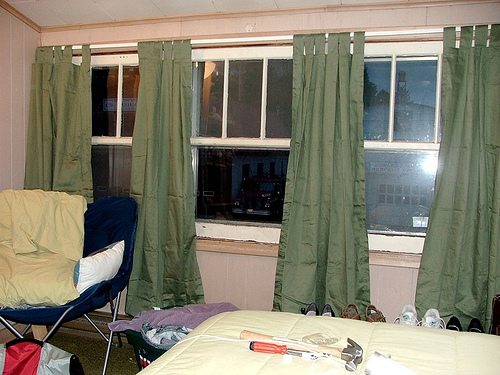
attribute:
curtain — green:
[122, 36, 204, 319]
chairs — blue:
[19, 151, 216, 373]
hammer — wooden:
[236, 327, 366, 374]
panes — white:
[36, 55, 495, 260]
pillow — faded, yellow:
[0, 183, 83, 310]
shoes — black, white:
[305, 299, 337, 318]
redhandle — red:
[251, 341, 288, 353]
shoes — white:
[403, 291, 447, 343]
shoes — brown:
[344, 301, 384, 323]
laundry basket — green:
[124, 319, 174, 371]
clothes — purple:
[101, 300, 242, 335]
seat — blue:
[38, 162, 173, 337]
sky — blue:
[365, 59, 442, 110]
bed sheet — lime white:
[407, 332, 452, 359]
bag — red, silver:
[1, 334, 88, 374]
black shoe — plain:
[468, 318, 483, 333]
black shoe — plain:
[445, 315, 461, 328]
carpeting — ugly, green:
[5, 331, 144, 373]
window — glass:
[191, 59, 223, 141]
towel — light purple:
[119, 305, 230, 341]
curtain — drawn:
[130, 42, 201, 314]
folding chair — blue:
[2, 196, 134, 373]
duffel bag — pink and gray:
[1, 339, 100, 372]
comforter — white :
[191, 299, 435, 373]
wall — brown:
[0, 7, 40, 344]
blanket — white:
[1, 186, 83, 303]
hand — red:
[245, 338, 290, 358]